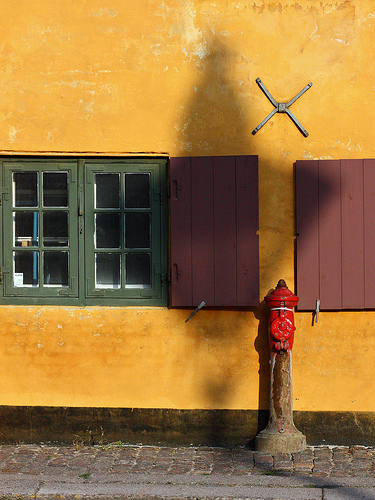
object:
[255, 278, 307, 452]
hydrant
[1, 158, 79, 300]
frame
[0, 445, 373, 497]
pavement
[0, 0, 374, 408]
wall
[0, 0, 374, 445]
building